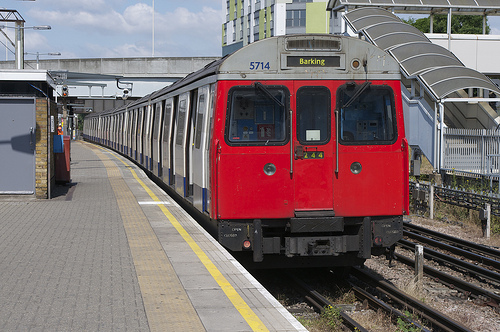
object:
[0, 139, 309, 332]
road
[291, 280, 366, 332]
railway line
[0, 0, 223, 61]
clouds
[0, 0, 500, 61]
sky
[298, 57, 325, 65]
green location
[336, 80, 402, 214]
doors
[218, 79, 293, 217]
doors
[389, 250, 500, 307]
railway track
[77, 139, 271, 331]
line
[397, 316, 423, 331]
grass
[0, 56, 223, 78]
bridge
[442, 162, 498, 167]
stairs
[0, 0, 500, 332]
station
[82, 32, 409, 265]
train